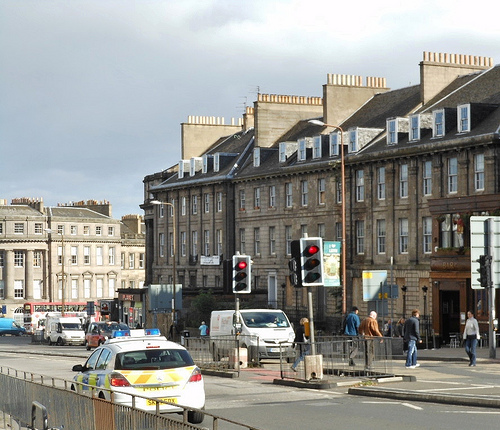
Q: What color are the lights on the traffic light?
A: Red.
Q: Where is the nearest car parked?
A: On the street.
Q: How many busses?
A: One.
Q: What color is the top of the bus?
A: Red.